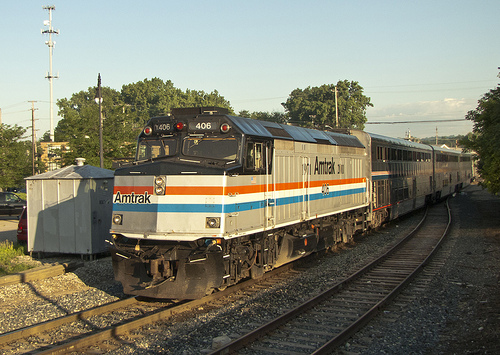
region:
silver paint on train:
[263, 138, 357, 233]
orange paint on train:
[228, 181, 273, 196]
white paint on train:
[206, 190, 254, 199]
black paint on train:
[228, 120, 286, 175]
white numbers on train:
[191, 101, 223, 132]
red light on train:
[218, 121, 258, 149]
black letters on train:
[119, 191, 164, 215]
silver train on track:
[96, 192, 356, 304]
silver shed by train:
[16, 154, 145, 272]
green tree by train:
[76, 105, 162, 168]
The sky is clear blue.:
[8, 2, 497, 98]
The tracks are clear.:
[35, 196, 450, 353]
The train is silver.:
[96, 107, 487, 287]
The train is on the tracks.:
[107, 104, 472, 281]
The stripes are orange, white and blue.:
[111, 166, 396, 219]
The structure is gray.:
[10, 164, 125, 266]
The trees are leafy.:
[60, 61, 349, 158]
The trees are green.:
[60, 81, 378, 176]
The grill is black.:
[95, 236, 222, 313]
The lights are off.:
[41, 2, 64, 146]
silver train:
[98, 111, 480, 256]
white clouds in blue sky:
[93, 12, 123, 40]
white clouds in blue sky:
[164, 25, 182, 50]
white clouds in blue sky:
[195, 29, 237, 73]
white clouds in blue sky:
[209, 15, 247, 77]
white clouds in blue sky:
[305, 4, 337, 58]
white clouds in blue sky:
[344, 26, 372, 51]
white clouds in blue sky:
[370, 6, 428, 68]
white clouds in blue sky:
[371, 72, 406, 92]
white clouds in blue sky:
[117, 14, 178, 48]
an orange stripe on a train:
[183, 185, 368, 194]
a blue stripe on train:
[194, 202, 301, 212]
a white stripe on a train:
[249, 190, 313, 194]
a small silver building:
[31, 165, 103, 268]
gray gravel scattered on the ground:
[414, 292, 463, 339]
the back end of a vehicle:
[18, 206, 30, 246]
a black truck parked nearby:
[4, 185, 21, 220]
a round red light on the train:
[141, 122, 151, 137]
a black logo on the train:
[314, 152, 344, 179]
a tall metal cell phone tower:
[31, 2, 68, 147]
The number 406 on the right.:
[195, 123, 215, 129]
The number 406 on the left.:
[156, 120, 171, 131]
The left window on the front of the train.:
[137, 136, 177, 158]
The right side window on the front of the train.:
[182, 132, 233, 160]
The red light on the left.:
[141, 121, 151, 132]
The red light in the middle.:
[175, 120, 185, 125]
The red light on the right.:
[220, 125, 227, 131]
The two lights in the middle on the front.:
[154, 172, 167, 197]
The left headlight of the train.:
[113, 215, 120, 224]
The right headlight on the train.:
[206, 218, 217, 228]